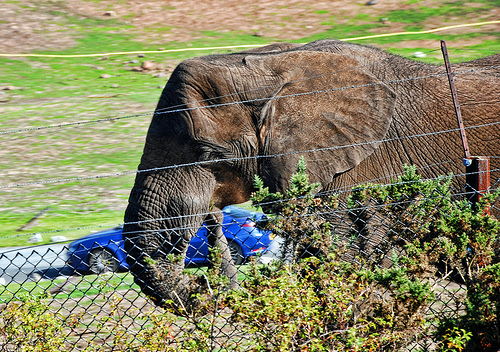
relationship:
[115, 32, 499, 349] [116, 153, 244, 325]
elephant has wrinkled trunk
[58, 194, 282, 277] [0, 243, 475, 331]
car on road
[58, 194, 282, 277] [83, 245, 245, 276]
car has black tires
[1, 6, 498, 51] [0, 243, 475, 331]
field behind road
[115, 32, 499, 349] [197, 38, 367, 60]
elephant has short hair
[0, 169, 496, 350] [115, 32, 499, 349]
bush in front elephant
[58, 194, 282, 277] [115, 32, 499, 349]
car behind elephant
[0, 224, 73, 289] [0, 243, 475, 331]
rocks are by road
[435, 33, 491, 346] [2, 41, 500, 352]
metal holding chain link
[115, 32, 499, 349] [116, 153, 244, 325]
elephant eating with trunk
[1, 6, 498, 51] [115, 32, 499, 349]
field behind elephant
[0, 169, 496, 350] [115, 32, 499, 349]
plants in front of elephant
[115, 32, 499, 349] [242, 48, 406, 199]
elephant has left ear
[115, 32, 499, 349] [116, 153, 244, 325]
elephant has trunk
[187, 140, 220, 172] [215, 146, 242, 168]
eye on left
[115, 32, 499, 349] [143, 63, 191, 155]
elephant has forehead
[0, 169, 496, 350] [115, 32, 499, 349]
bush near elephant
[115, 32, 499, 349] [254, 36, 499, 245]
elephant has body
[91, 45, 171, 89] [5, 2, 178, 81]
rocks are on hill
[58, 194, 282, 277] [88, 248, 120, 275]
car has black tires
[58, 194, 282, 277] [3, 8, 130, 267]
car in background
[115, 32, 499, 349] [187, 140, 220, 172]
elephant has eye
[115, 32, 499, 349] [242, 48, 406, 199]
elephant has ear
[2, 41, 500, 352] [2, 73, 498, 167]
chain link has chain link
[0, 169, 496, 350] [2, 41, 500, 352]
bush growing on chain link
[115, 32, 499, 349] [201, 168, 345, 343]
elephant eating plant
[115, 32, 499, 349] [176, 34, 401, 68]
elephant has back hair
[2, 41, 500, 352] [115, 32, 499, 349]
chain link on right of elephan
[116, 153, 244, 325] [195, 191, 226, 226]
wrinkled trunk in mouth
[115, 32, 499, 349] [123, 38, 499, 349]
fence front elephant